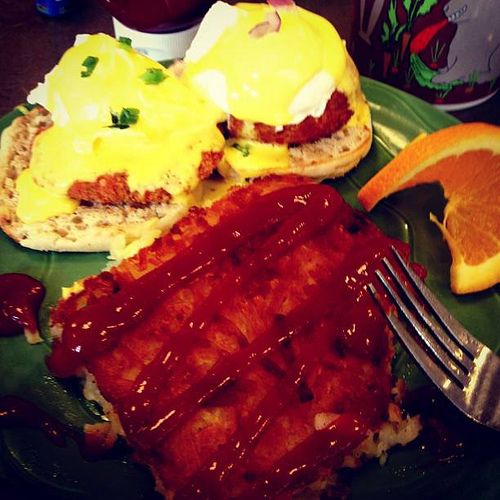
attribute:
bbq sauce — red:
[228, 292, 284, 345]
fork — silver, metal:
[365, 242, 499, 432]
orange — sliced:
[358, 120, 499, 294]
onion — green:
[109, 107, 139, 130]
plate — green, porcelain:
[0, 74, 498, 498]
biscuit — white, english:
[0, 114, 204, 256]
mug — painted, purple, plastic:
[354, 0, 500, 113]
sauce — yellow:
[50, 6, 370, 215]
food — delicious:
[0, 3, 500, 497]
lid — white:
[111, 17, 200, 64]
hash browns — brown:
[62, 184, 411, 499]